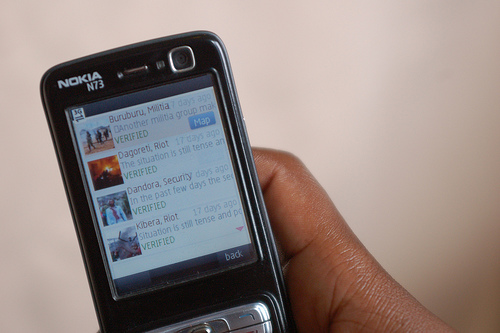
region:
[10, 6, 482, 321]
Black and silver cell phone.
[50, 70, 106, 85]
The word NOKIA in white letters.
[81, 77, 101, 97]
N73 in white letters.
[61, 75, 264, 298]
The screen on a cell phone.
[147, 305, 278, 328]
Part of silver keypad.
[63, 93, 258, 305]
Four pictures on a cell phone.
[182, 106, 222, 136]
A blue square with white writing.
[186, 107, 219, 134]
The word Map in white letters.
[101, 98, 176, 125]
The words Buruburu, Militia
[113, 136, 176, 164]
The words Dagoreti, Riot.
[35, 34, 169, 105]
"Nokia N73" is on the phone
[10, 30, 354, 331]
This phone is black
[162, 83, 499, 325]
The person is of African decent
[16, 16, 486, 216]
A white wall in the background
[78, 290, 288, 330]
The buttons are silver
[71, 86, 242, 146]
"Buruburu, Militia" is the word here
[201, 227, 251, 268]
This is the back option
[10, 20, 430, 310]
The person is holding the phone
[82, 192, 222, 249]
"Kibera Riot" is on the phone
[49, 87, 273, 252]
The background is white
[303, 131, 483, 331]
Face of a person's hand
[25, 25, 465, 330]
Cellphone in man's hand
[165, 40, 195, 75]
Camera on mobile phone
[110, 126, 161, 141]
Word 'verified' on screen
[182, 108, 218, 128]
Blue icon on screen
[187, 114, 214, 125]
White lettering in blue icon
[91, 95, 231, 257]
News feed on social network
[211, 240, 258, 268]
Black icon on mobile phone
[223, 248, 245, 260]
White lettering in black icon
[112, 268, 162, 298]
Blank black icon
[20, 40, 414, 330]
A person is holding a phone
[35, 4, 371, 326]
A nokia phone is in the photo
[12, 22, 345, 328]
A black Nokia phone is in the photo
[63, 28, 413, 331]
The cell phone is on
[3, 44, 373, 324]
The cell phone is black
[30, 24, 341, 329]
The number and letter N73 is on the phone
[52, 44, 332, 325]
On the phone's screen is the word map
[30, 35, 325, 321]
In write letters on the phone is says N73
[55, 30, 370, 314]
Nokia is written in white letters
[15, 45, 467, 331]
One hand is holding the phone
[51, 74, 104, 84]
Nokia insignia on phone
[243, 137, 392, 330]
hand of phone user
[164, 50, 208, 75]
camera lense of cell phone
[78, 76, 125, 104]
identification numbers on the phone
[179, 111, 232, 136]
help button for the phone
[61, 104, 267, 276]
screen on the cell phone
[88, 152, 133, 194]
Picture identification of the person he is talking to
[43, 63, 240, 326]
cell phone from Nokia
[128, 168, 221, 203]
Name of one of his contacts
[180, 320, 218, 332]
part of the phone you talk into